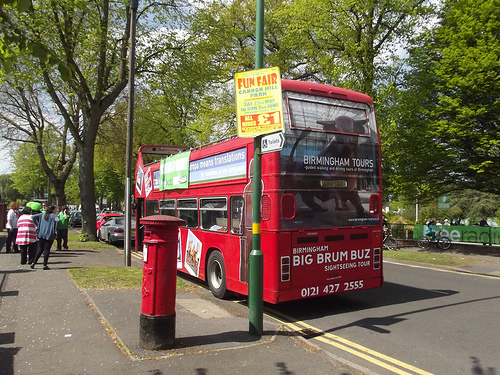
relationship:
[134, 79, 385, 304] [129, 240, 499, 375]
bus parked on street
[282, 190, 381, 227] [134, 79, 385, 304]
windshield of bus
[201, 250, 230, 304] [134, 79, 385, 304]
wheel of bus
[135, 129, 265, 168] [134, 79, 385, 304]
sitting area of bus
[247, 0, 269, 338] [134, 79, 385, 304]
pole beside bus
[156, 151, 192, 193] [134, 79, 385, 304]
banner on side of bus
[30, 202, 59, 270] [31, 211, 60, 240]
man wearing sweater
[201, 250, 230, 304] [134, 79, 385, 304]
wheel on bus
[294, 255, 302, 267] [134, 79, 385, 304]
letter on bus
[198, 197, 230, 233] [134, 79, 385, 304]
window on bus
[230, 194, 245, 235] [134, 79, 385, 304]
window on bus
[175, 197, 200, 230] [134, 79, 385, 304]
window on bus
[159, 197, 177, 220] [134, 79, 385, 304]
window on bus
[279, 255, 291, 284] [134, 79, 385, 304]
light on bus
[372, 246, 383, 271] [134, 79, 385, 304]
light on bus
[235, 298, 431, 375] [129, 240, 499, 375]
lines in street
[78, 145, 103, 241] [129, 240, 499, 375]
tree trunk near street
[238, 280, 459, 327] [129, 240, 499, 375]
shadow on street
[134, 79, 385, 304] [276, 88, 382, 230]
bus has advertisements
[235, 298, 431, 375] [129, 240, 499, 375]
lines on edge of street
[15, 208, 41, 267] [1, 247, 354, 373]
person standing on sidewalk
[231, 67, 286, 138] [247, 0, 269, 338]
sign posted to pole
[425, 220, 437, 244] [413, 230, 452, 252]
person riding bike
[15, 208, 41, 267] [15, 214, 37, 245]
person has sweater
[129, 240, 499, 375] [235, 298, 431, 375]
street has lines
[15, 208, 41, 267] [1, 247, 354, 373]
person on sidewalk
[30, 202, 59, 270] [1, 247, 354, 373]
man on sidewalk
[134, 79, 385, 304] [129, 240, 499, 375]
bus on street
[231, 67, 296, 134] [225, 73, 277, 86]
sign says "fun fair"